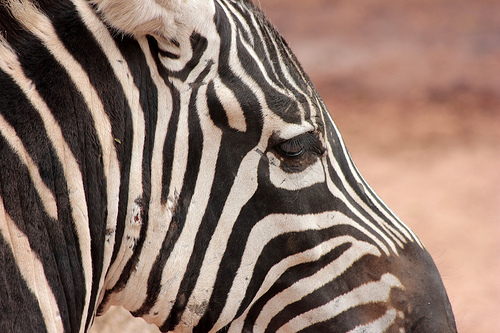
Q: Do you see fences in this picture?
A: No, there are no fences.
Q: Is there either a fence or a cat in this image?
A: No, there are no fences or cats.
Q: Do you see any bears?
A: No, there are no bears.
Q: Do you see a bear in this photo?
A: No, there are no bears.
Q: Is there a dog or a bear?
A: No, there are no bears or dogs.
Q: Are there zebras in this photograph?
A: Yes, there is a zebra.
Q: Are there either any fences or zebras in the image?
A: Yes, there is a zebra.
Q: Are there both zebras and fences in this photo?
A: No, there is a zebra but no fences.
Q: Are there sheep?
A: No, there are no sheep.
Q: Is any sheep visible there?
A: No, there is no sheep.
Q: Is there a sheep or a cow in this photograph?
A: No, there are no sheep or cows.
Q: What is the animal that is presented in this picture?
A: The animal is a zebra.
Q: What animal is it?
A: The animal is a zebra.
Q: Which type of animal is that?
A: This is a zebra.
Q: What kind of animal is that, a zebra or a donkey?
A: This is a zebra.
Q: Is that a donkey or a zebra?
A: That is a zebra.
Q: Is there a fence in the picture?
A: No, there are no fences.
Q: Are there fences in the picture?
A: No, there are no fences.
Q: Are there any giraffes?
A: No, there are no giraffes.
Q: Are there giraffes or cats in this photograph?
A: No, there are no giraffes or cats.